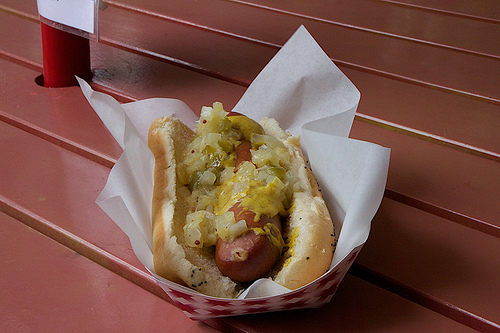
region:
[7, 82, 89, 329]
a red patio table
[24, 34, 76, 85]
red pole of a parasol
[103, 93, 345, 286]
a hot dog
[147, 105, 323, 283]
a hot dog with mustard, onions and relish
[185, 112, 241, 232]
mustard and relish and onions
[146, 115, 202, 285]
hot dog bun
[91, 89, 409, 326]
a hod dog in a paper tray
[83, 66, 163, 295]
white paper on a paper tray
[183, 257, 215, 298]
poppy seeds on a hot dog bun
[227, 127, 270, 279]
a frank sausage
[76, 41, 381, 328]
hot dog with toppings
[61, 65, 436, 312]
hot dog on white paper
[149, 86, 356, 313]
hot dog with onions and mustard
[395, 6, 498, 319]
section of red table top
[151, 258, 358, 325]
red and white paper basket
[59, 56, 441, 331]
hot dog on a red table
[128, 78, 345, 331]
hot dog in a bun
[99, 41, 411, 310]
hot dog with mustard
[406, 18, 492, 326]
red plastic table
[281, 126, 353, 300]
hot dog bun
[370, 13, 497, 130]
The table is red.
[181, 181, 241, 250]
Diced onions on the hotdog.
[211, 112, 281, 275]
Hotdog in a bun.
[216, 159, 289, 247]
Mustard on the hotdog.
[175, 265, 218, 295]
Poppy seeds on the bun.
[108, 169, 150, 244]
The paper is white.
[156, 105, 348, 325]
Hotdog is in a box.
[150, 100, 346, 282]
Hotdog is on a paper.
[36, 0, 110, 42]
White sign on umbrella pole.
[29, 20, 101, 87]
The umbrella pole is red.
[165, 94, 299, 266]
A hotdog sandwich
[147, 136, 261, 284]
A hotdog sandwich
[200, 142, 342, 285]
A hotdog sandwich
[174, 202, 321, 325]
A hotdog sandwich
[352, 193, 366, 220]
the tissue is white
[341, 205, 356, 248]
the tissue is white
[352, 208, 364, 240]
the tissue is white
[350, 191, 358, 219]
the tissue is white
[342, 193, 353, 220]
the tissue is white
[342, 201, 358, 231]
the tissue is white